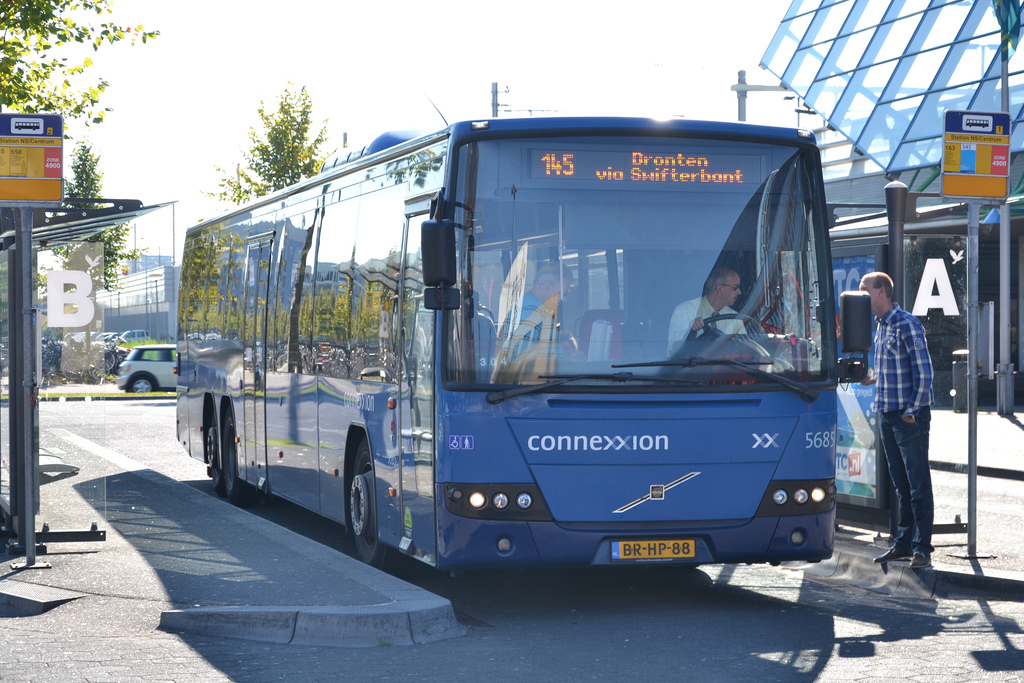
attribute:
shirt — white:
[669, 301, 747, 349]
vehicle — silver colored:
[115, 338, 176, 395]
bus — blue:
[169, 111, 878, 578]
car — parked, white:
[113, 336, 181, 391]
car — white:
[109, 340, 181, 392]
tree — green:
[201, 78, 338, 210]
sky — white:
[1, 1, 984, 261]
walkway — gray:
[3, 428, 393, 612]